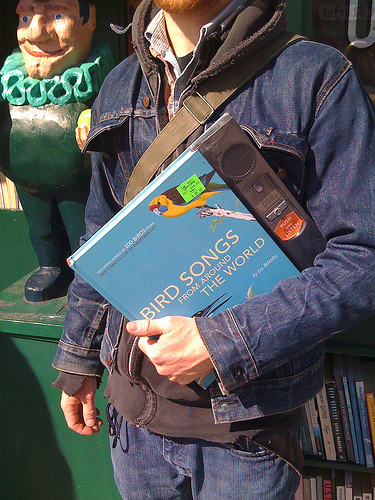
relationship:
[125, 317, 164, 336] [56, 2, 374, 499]
thumb of person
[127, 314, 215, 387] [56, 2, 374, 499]
hand of person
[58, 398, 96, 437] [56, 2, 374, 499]
finger of person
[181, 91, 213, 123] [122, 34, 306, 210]
buckle on bag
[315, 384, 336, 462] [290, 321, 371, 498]
book on shelf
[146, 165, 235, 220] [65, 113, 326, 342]
bird on book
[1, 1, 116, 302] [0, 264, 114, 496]
statue on box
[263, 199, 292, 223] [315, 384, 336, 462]
button on book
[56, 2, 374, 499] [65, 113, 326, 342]
man holding book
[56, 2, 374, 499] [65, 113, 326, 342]
person holding book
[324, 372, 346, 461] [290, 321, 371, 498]
book on shelf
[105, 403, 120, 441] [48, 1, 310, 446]
string on shirt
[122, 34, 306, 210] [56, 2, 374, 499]
strap on person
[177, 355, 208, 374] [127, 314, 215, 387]
vein on hand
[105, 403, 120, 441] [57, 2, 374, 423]
string on jacket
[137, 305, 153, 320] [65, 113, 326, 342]
letter on book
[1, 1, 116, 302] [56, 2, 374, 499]
statue beside person